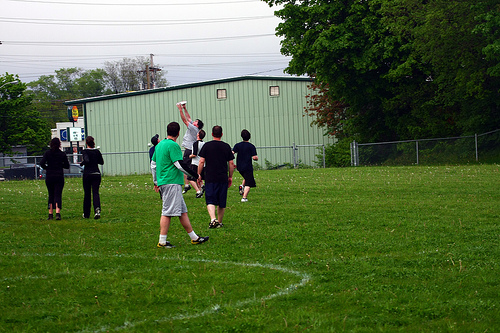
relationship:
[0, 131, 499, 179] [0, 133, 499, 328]
fence surfing park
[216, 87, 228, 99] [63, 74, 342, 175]
window on side of building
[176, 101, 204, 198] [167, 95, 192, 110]
man catching frisbee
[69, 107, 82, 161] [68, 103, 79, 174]
advertisements on pole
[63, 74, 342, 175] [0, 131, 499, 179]
building on side of fence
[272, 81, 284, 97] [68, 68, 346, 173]
window on a building